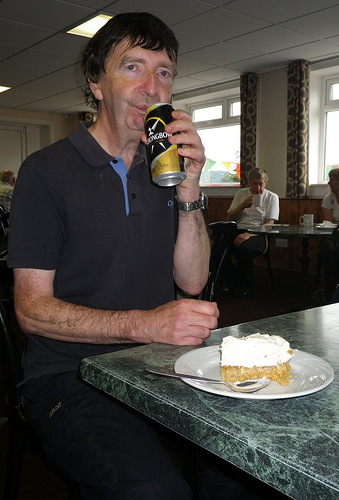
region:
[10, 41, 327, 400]
an old man eating a piece of cake and drinking a beer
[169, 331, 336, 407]
a piece of cake with white frosting and nuts on a white plate with a silver spoon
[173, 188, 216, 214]
a silver metal wrist watch on the man's wrist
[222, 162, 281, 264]
an old man in a white shirt drinking a coffee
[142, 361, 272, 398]
a large silver spoon on a plate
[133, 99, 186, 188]
a can of Strongbow the man is about to drink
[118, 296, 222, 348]
the man's right hand resting on a green table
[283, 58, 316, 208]
beige curtains with a circular pattern on them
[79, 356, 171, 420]
the edge of a green marble painted table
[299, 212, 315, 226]
a white coffee mug on a table nearby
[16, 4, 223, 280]
man drinking from a can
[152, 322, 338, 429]
slice of pie on round plate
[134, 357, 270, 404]
spoon on dessert plate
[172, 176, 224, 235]
man wearing silver watch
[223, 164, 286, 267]
man drinking cup of coffee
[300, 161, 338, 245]
woman talking to man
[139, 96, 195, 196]
black and gold can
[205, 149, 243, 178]
string of flags out the window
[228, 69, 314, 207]
brown curtains hanging from window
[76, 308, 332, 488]
green marble top table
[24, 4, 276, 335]
a man drinking a can drink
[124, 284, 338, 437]
a cake on plate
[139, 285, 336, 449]
a plate with cake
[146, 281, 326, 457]
a plate with spoon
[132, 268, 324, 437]
a plate with cake and spoon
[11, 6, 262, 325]
a man with long hair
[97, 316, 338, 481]
a plate on a table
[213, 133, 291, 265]
an old man drinking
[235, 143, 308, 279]
a man holding a white cup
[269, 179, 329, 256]
a cup on a table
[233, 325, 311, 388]
A slice of cake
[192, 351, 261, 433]
A slice of cake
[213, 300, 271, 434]
A slice of cake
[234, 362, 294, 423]
A slice of cake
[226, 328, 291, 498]
A slice of cake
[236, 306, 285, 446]
A slice of cake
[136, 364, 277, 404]
A sliver spoon on a plate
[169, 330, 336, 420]
A white plate with a slice of pie on it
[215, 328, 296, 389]
A slice of pie on a white plate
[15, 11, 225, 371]
A man drinking from can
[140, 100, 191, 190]
A canned drink being drunk by a man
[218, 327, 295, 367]
White meringue on a pie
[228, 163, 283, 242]
A man wearing a white tee shirt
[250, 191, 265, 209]
A white coffee cup being drunk from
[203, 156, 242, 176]
A stringer of colored flags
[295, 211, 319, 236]
A white coffee cup on a table